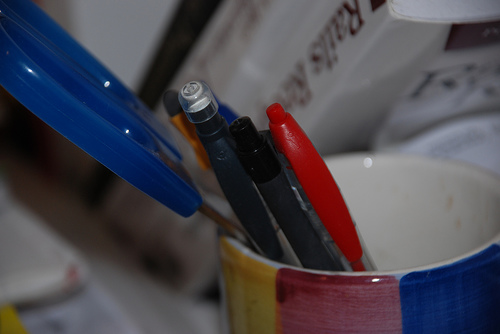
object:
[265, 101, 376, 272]
pen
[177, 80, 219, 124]
cap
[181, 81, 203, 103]
eraser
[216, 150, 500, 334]
coffee mug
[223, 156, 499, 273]
mouth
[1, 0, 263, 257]
scissors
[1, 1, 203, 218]
handle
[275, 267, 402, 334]
paint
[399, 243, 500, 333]
paint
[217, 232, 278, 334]
paint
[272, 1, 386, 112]
writing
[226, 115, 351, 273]
pen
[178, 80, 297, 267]
pencil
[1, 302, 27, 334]
paper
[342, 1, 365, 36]
letter